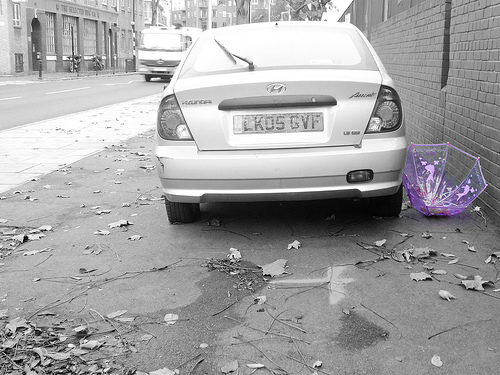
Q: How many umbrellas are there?
A: One.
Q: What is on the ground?
A: An umbrella.